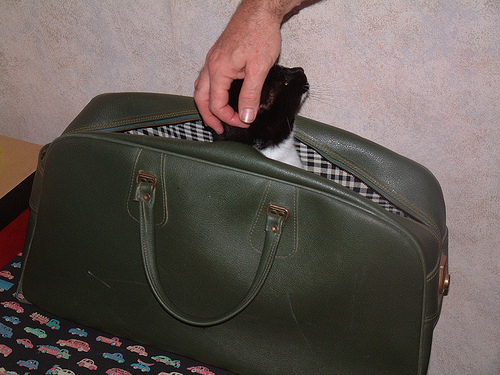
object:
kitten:
[206, 65, 310, 172]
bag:
[19, 93, 451, 375]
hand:
[193, 17, 282, 135]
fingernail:
[241, 107, 255, 123]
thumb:
[237, 63, 273, 124]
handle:
[132, 172, 288, 327]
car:
[76, 358, 96, 371]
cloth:
[0, 248, 227, 374]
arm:
[232, 0, 304, 25]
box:
[0, 134, 45, 271]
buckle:
[437, 254, 451, 295]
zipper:
[60, 108, 443, 255]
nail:
[215, 131, 219, 135]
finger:
[193, 68, 225, 135]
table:
[0, 134, 46, 200]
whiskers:
[295, 83, 349, 113]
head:
[211, 63, 309, 149]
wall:
[0, 0, 498, 374]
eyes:
[255, 84, 274, 105]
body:
[349, 0, 373, 1]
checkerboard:
[120, 119, 214, 143]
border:
[0, 206, 32, 271]